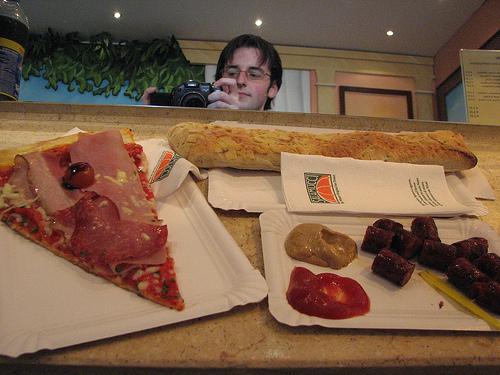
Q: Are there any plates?
A: Yes, there is a plate.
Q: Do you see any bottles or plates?
A: Yes, there is a plate.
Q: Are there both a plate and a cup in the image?
A: No, there is a plate but no cups.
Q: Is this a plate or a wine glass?
A: This is a plate.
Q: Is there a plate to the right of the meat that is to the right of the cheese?
A: Yes, there is a plate to the right of the meat.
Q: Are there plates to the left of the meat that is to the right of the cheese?
A: No, the plate is to the right of the meat.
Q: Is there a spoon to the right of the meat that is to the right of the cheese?
A: No, there is a plate to the right of the meat.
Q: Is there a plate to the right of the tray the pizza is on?
A: Yes, there is a plate to the right of the tray.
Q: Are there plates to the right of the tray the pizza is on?
A: Yes, there is a plate to the right of the tray.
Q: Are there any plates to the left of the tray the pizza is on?
A: No, the plate is to the right of the tray.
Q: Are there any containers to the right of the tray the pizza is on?
A: No, there is a plate to the right of the tray.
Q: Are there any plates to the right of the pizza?
A: Yes, there is a plate to the right of the pizza.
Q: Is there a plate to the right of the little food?
A: Yes, there is a plate to the right of the pizza.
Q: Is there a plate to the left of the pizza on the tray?
A: No, the plate is to the right of the pizza.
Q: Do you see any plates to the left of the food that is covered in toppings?
A: No, the plate is to the right of the pizza.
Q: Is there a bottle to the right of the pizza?
A: No, there is a plate to the right of the pizza.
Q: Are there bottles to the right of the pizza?
A: No, there is a plate to the right of the pizza.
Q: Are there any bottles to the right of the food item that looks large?
A: No, there is a plate to the right of the pizza.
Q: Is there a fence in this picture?
A: No, there are no fences.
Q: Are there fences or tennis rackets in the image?
A: No, there are no fences or tennis rackets.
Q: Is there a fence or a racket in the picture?
A: No, there are no fences or rackets.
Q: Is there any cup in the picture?
A: No, there are no cups.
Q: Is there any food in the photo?
A: Yes, there is food.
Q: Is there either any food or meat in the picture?
A: Yes, there is food.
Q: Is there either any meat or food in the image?
A: Yes, there is food.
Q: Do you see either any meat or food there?
A: Yes, there is food.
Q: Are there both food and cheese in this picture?
A: Yes, there are both food and cheese.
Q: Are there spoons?
A: No, there are no spoons.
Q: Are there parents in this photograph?
A: No, there are no parents.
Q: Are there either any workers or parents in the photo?
A: No, there are no parents or workers.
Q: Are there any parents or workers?
A: No, there are no parents or workers.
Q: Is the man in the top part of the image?
A: Yes, the man is in the top of the image.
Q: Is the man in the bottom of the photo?
A: No, the man is in the top of the image.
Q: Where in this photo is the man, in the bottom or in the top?
A: The man is in the top of the image.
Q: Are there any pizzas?
A: Yes, there is a pizza.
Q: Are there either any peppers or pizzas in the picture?
A: Yes, there is a pizza.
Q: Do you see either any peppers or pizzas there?
A: Yes, there is a pizza.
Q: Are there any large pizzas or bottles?
A: Yes, there is a large pizza.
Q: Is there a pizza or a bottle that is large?
A: Yes, the pizza is large.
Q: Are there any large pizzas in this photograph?
A: Yes, there is a large pizza.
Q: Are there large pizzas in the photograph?
A: Yes, there is a large pizza.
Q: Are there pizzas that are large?
A: Yes, there is a pizza that is large.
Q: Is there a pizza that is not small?
A: Yes, there is a large pizza.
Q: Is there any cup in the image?
A: No, there are no cups.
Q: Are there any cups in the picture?
A: No, there are no cups.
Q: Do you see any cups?
A: No, there are no cups.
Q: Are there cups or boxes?
A: No, there are no cups or boxes.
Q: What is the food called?
A: The food is a pizza.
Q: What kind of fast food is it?
A: The food is a pizza.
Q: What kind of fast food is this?
A: This is a pizza.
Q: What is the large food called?
A: The food is a pizza.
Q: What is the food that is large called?
A: The food is a pizza.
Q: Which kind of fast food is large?
A: The fast food is a pizza.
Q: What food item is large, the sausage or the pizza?
A: The pizza is large.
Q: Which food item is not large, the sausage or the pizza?
A: The sausage is not large.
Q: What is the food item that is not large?
A: The food item is a sausage.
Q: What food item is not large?
A: The food item is a sausage.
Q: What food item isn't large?
A: The food item is a sausage.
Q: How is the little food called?
A: The food is a pizza.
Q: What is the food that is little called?
A: The food is a pizza.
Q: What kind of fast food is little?
A: The fast food is a pizza.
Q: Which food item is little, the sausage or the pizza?
A: The pizza is little.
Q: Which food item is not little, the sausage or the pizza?
A: The sausage is not little.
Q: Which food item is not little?
A: The food item is a sausage.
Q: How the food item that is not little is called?
A: The food item is a sausage.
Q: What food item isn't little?
A: The food item is a sausage.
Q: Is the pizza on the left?
A: Yes, the pizza is on the left of the image.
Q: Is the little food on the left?
A: Yes, the pizza is on the left of the image.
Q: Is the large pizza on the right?
A: No, the pizza is on the left of the image.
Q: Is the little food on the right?
A: No, the pizza is on the left of the image.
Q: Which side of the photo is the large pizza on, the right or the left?
A: The pizza is on the left of the image.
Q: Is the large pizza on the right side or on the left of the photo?
A: The pizza is on the left of the image.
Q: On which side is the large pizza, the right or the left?
A: The pizza is on the left of the image.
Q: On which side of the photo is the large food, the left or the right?
A: The pizza is on the left of the image.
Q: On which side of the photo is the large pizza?
A: The pizza is on the left of the image.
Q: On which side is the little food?
A: The pizza is on the left of the image.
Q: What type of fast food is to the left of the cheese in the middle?
A: The food is a pizza.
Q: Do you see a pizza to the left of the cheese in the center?
A: Yes, there is a pizza to the left of the cheese.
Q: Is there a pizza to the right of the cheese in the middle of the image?
A: No, the pizza is to the left of the cheese.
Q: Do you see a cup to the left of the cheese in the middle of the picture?
A: No, there is a pizza to the left of the cheese.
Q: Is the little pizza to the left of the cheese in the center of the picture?
A: Yes, the pizza is to the left of the cheese.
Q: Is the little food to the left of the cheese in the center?
A: Yes, the pizza is to the left of the cheese.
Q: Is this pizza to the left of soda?
A: No, the pizza is to the left of the cheese.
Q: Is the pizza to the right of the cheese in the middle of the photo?
A: No, the pizza is to the left of the cheese.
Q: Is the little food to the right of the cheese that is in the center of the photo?
A: No, the pizza is to the left of the cheese.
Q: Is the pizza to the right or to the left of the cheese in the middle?
A: The pizza is to the left of the cheese.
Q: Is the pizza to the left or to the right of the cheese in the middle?
A: The pizza is to the left of the cheese.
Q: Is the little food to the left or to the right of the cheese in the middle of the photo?
A: The pizza is to the left of the cheese.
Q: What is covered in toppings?
A: The pizza is covered in toppings.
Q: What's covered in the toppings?
A: The pizza is covered in toppings.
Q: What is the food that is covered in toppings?
A: The food is a pizza.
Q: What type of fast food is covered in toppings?
A: The food is a pizza.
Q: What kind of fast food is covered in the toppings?
A: The food is a pizza.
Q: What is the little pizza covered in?
A: The pizza is covered in toppings.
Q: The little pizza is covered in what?
A: The pizza is covered in toppings.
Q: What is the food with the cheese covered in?
A: The pizza is covered in toppings.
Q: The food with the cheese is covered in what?
A: The pizza is covered in toppings.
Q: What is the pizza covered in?
A: The pizza is covered in toppings.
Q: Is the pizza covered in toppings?
A: Yes, the pizza is covered in toppings.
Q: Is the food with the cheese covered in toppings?
A: Yes, the pizza is covered in toppings.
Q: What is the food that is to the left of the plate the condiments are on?
A: The food is a pizza.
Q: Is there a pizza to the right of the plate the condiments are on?
A: No, the pizza is to the left of the plate.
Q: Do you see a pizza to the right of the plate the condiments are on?
A: No, the pizza is to the left of the plate.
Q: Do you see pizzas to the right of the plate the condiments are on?
A: No, the pizza is to the left of the plate.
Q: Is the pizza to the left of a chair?
A: No, the pizza is to the left of the plate.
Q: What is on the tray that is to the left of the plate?
A: The pizza is on the tray.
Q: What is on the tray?
A: The pizza is on the tray.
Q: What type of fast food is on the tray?
A: The food is a pizza.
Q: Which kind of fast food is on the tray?
A: The food is a pizza.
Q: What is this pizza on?
A: The pizza is on the tray.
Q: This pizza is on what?
A: The pizza is on the tray.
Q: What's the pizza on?
A: The pizza is on the tray.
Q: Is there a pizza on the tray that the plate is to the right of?
A: Yes, there is a pizza on the tray.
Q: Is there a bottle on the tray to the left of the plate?
A: No, there is a pizza on the tray.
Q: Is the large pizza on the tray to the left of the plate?
A: Yes, the pizza is on the tray.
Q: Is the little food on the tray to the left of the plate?
A: Yes, the pizza is on the tray.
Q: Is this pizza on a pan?
A: No, the pizza is on the tray.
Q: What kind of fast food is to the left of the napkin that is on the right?
A: The food is a pizza.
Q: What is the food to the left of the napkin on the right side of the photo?
A: The food is a pizza.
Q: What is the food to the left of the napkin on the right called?
A: The food is a pizza.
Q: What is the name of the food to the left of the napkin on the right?
A: The food is a pizza.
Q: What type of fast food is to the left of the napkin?
A: The food is a pizza.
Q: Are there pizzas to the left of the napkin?
A: Yes, there is a pizza to the left of the napkin.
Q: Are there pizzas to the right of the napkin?
A: No, the pizza is to the left of the napkin.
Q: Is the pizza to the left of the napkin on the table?
A: Yes, the pizza is to the left of the napkin.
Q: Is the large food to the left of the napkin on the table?
A: Yes, the pizza is to the left of the napkin.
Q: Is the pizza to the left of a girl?
A: No, the pizza is to the left of the napkin.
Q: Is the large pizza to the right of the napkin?
A: No, the pizza is to the left of the napkin.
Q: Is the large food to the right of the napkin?
A: No, the pizza is to the left of the napkin.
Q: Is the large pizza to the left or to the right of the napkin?
A: The pizza is to the left of the napkin.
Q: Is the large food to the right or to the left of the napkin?
A: The pizza is to the left of the napkin.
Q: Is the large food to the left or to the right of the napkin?
A: The pizza is to the left of the napkin.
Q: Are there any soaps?
A: No, there are no soaps.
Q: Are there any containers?
A: No, there are no containers.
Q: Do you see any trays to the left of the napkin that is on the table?
A: Yes, there is a tray to the left of the napkin.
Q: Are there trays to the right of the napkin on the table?
A: No, the tray is to the left of the napkin.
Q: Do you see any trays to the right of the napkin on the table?
A: No, the tray is to the left of the napkin.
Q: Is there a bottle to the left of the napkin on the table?
A: No, there is a tray to the left of the napkin.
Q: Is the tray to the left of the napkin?
A: Yes, the tray is to the left of the napkin.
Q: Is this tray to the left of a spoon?
A: No, the tray is to the left of the napkin.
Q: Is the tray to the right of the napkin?
A: No, the tray is to the left of the napkin.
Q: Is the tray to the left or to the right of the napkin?
A: The tray is to the left of the napkin.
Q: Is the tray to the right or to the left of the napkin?
A: The tray is to the left of the napkin.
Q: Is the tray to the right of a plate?
A: No, the tray is to the left of a plate.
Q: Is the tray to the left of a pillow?
A: No, the tray is to the left of the plate.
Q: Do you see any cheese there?
A: Yes, there is cheese.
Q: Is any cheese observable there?
A: Yes, there is cheese.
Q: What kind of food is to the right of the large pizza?
A: The food is cheese.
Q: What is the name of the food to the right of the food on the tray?
A: The food is cheese.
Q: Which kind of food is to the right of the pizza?
A: The food is cheese.